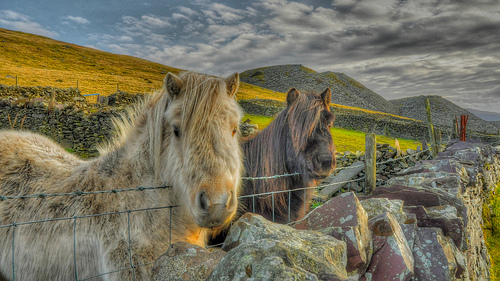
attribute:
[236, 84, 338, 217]
horse — gray, furry, brown, looking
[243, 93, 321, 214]
hair — long, brown, dark brown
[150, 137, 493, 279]
wall — stone, big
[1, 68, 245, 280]
horse — white, hairy, beige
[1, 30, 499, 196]
hillside — grass covered, flower covered, grassy, brown, golden brown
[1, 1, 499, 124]
sky — cloudy, blue, grey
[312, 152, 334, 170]
nose — in front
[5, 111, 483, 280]
fence — wire, grilled, grey, metal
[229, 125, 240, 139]
left eye — closed, brown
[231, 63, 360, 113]
hill — grassy